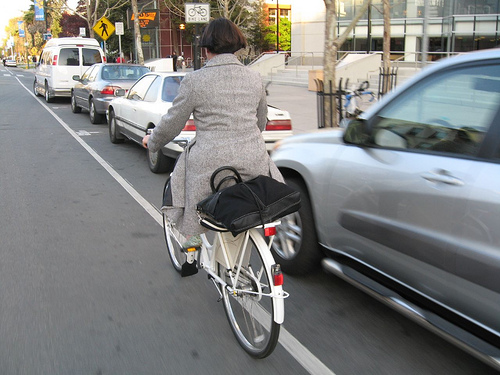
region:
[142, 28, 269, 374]
lady driving a bicycle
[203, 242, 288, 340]
the bicycle is white in color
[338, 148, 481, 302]
the car is silvery in color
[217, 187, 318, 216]
the bag is black in color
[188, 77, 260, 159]
the jacket is grey in color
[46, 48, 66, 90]
the car is white in color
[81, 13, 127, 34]
th poster is yellow in color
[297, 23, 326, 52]
the roof is white in color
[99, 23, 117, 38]
the poster has picture in black color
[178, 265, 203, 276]
the hoes are black in color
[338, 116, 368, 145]
the side view mirror on the car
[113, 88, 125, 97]
the side view mirror on the car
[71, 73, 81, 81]
the side view mirror on the car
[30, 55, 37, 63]
the side view mirror on the car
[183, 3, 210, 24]
the white bike sign on the pole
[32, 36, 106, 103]
the parked white van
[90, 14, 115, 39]
the yellow street sign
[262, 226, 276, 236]
the light on the bike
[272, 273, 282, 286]
the light on the bike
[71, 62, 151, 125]
the parked car behind the van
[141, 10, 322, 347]
PERSON RIDING A WHITE BIKE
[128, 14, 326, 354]
PERSON RIDING BIKE TO WORK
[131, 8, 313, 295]
PERSON WITH SHORT DARK HAIR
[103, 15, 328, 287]
PERSON WEARING LONG GREY COAT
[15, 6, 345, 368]
PERSON RIDING BIKE IN THE STREET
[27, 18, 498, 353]
VEHICLES PARKED ON SIDE OF ROAD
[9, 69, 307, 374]
LINE SEPARATING PARKING FROM ROAD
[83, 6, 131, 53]
YELLOW CAUTION SIGN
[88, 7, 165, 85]
YELLOW CAUTION SIGN FOR PEDESTRIANS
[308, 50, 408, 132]
BLACK GARBAGE CANS ON SIDEWALK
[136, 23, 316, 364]
a woman riding a bicycle in the street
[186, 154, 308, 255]
black bag on the back of the bicycle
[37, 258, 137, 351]
black asphalt surface of the road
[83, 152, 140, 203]
white line painted on the road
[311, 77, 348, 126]
black fence surrounding a tree trunk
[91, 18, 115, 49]
yellow and black street sign on the sidewalk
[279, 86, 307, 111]
grey concrete surface of the sidewalk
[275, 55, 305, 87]
grey concrete stairs next to the building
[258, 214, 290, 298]
red reflectors on the back of a bicycle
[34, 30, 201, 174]
several cars parked on the street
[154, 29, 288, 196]
this is a a lady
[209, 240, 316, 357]
this is a bicycle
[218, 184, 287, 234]
this is a bag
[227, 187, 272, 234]
the bag is black in color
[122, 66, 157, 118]
this is a car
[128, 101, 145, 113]
the car is white in color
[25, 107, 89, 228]
this is the road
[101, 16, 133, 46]
this is a tree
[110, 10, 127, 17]
the leaves are green in color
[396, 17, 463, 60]
this is a building